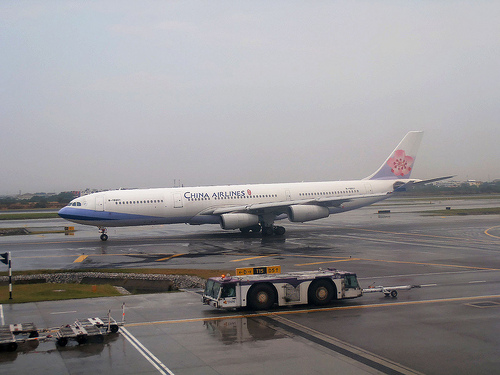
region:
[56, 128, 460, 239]
a blue and white jet from China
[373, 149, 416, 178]
a pink flower sits on purple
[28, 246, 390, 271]
yellow paint mark lines on the runway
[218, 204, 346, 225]
two engines mounted to one wing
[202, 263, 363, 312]
emergency vehicle parked near the plane.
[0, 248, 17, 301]
lights on a black and white pole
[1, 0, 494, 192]
overcast grey sky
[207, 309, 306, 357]
reflection of truck on wet pavement.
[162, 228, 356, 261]
plane refected in pavement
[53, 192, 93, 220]
a cockpit window in the plane.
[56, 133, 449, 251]
large white plane on tarmac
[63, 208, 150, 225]
blue line on bottom of plane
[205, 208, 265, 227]
white engine below plane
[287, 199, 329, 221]
white engine below plane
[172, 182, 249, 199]
blue writing on plane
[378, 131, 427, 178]
pink flower on side of plane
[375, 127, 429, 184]
white tail fin behind plane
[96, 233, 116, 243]
black wheel on front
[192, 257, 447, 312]
white vehicle on tarmac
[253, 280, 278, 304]
wheel on side of vehicle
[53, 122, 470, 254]
China Airlines jet on runway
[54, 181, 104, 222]
nose and cockpit of passenger jet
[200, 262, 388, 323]
airport ground support equipment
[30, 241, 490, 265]
wet airport runway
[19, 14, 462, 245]
passenger jet against overcast grey sky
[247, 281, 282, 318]
large wheel on airport support equipment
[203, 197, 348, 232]
jet engines on passenger jet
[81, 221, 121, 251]
passenger jet landing gear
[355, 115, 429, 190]
vertical stabilizer on passenger jet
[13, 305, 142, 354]
airport container and pallet loader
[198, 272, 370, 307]
a long truck sitting on the tarmack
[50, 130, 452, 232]
a long plane on the runway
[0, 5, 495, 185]
the gloomy sky above the plane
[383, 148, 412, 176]
the flower on the end of the plane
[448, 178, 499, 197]
the trees off in the back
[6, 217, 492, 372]
the tarmac and runways for the planes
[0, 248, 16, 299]
a pole with some lights on i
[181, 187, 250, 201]
the writing on the side of the plane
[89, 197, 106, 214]
the door on the plane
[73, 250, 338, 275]
some lines on the ground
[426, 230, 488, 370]
The ground is made of asphalt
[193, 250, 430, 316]
A truck on the ground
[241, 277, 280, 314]
The front wheel of the truck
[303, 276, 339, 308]
The back wheel of the truck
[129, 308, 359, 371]
The ground is wet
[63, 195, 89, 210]
The cockpit of the plane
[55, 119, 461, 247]
The plane is on the ground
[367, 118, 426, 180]
The tail of the plane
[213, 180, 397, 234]
The side wing of the plane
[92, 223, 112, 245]
The front wheel of the plane